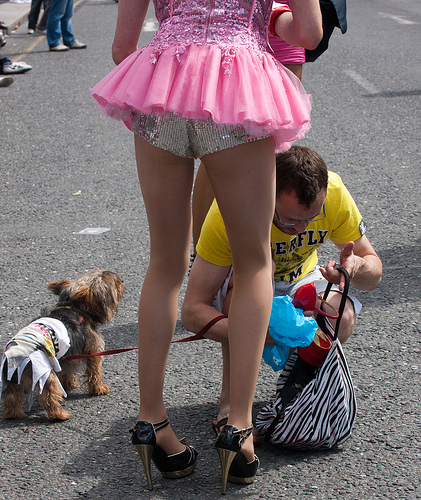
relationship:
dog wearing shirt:
[3, 267, 123, 422] [0, 314, 71, 394]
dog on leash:
[3, 267, 123, 422] [60, 314, 229, 362]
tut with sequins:
[85, 49, 300, 130] [131, 89, 255, 128]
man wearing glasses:
[180, 143, 383, 447] [280, 206, 328, 230]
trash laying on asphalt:
[80, 221, 117, 247] [42, 194, 122, 257]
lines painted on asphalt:
[3, 44, 54, 79] [3, 84, 74, 129]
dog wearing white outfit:
[4, 259, 111, 422] [7, 316, 57, 387]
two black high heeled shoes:
[88, 386, 280, 497] [113, 454, 243, 497]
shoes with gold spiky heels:
[129, 421, 200, 493] [137, 458, 235, 492]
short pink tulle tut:
[82, 44, 326, 197] [85, 27, 312, 157]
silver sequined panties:
[97, 50, 297, 160] [131, 101, 271, 161]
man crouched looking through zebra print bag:
[198, 138, 404, 425] [256, 323, 362, 450]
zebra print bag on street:
[258, 258, 372, 479] [147, 377, 407, 500]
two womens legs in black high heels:
[120, 124, 297, 474] [124, 403, 253, 500]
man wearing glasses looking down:
[180, 143, 383, 447] [217, 184, 363, 404]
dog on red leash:
[3, 267, 123, 422] [99, 334, 131, 369]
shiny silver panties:
[141, 123, 230, 144] [145, 101, 215, 140]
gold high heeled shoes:
[132, 443, 234, 500] [91, 398, 266, 500]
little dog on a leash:
[4, 244, 146, 442] [97, 340, 129, 366]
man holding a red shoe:
[180, 143, 383, 447] [278, 285, 338, 353]